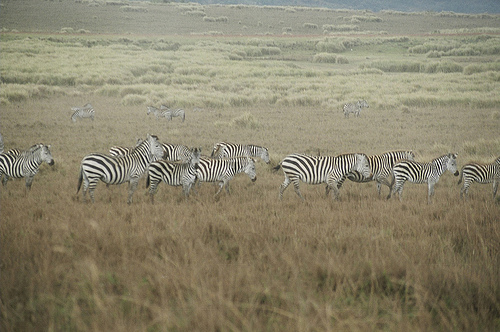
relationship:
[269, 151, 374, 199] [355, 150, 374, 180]
zebra has head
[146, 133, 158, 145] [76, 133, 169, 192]
ear of a zebra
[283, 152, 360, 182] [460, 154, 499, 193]
stripes on zebra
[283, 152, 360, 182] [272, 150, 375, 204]
stripes on zebra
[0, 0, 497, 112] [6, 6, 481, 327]
bushes on field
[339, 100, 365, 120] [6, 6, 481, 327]
zebra standing on field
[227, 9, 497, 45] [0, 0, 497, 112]
river behind green bushes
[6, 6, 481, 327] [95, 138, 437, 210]
field with standing zebras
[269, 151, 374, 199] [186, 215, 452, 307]
zebra in a field of tall grass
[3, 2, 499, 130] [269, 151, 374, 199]
vegetation growing far behind zebra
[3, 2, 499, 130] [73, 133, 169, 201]
vegetation growing far behind zebra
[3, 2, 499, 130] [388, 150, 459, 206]
vegetation growing far behind zebra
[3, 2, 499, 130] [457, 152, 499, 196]
vegetation growing far behind zebra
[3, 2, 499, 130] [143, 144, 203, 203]
vegetation growing far behind zebra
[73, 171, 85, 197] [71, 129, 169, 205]
tail of zebra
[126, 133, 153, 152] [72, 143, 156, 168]
mane on back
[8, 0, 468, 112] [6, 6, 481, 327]
bushes in field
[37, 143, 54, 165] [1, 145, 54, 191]
head of zebra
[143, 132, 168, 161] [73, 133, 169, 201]
head of zebra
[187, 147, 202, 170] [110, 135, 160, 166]
head of zebra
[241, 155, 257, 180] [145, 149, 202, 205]
head of zebra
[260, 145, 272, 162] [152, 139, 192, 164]
head of zebra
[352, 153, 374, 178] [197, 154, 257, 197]
head of zebra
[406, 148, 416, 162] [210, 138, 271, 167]
head of zebra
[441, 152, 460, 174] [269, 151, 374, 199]
head of zebra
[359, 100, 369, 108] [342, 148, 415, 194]
head of zebra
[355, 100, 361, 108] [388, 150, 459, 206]
head of zebra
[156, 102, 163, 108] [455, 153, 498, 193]
head of zebra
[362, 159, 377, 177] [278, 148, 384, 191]
eye of zebra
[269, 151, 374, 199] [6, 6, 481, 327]
zebra in field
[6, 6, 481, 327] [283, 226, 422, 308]
field of grass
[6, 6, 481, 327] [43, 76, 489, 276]
field with zebras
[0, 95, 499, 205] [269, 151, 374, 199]
heard of zebra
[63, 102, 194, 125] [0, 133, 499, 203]
zebras behind zebras